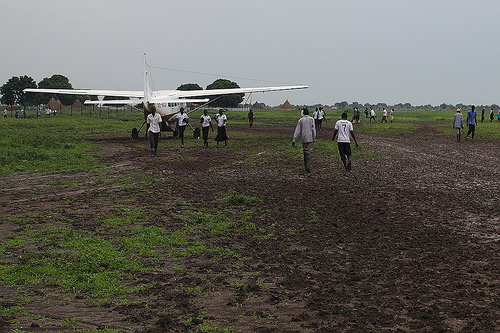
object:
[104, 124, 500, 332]
mud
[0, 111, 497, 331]
field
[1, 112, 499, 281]
grass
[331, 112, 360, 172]
man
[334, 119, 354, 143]
shirt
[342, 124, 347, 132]
7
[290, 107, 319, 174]
man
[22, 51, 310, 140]
plane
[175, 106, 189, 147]
people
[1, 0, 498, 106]
sky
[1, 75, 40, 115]
trees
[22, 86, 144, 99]
wing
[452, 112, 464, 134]
outfit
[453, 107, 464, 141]
person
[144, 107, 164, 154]
person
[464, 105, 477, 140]
person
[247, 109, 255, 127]
person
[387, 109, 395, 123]
person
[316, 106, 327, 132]
person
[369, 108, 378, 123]
person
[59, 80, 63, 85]
leaves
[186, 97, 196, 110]
propeller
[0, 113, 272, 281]
runway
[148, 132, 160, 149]
pants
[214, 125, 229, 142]
skirt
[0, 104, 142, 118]
fence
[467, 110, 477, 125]
shirt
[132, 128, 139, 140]
wheels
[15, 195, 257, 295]
patches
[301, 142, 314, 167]
pants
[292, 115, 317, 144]
shirt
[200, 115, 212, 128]
shirts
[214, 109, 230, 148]
girls